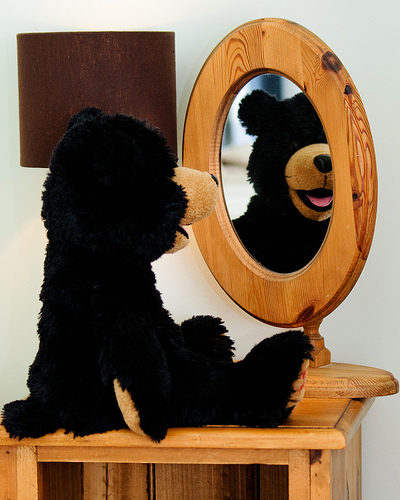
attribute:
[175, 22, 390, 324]
frame — brown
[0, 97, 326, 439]
doll — black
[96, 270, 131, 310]
teddy — black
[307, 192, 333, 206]
tongue — pink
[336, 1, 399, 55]
wall — white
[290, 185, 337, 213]
mouth — open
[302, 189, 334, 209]
tongue — pink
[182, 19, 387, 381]
frame — curved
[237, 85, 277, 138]
ear — round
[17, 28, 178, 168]
shade — brown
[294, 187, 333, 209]
tongue — pink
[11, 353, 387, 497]
table — wooden